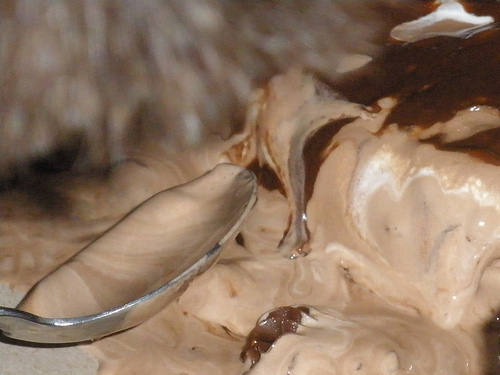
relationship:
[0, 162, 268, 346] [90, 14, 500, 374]
spoon in cream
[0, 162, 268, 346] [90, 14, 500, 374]
spoon on cream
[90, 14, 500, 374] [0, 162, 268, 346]
cream on spoon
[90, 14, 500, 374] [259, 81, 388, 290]
cream moving down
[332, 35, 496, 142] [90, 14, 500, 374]
chocolate covered cream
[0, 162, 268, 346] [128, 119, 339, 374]
spoon with brown dessert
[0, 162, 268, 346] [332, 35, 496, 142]
spoon in chocolate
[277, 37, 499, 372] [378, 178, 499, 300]
dark brown on light brown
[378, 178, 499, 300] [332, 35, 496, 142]
light brown under dark brown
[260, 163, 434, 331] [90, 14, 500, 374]
creamy chocolate dessert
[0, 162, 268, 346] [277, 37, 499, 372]
spoon in ice cream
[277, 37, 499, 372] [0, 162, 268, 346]
ice cream on spoon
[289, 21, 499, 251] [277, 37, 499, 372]
syrup in ice cream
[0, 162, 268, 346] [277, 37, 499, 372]
spoon with ice cream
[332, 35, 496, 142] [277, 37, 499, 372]
chocolate melted ice cream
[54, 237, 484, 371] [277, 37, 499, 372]
vanilla melted ice cream